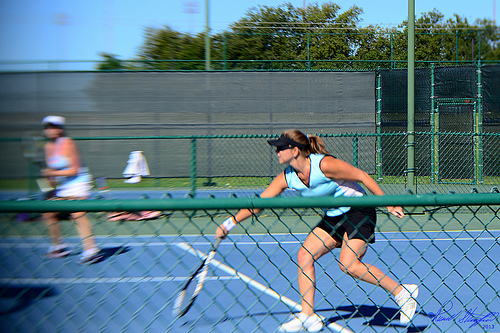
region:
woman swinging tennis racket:
[174, 126, 424, 330]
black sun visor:
[264, 127, 319, 154]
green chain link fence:
[46, 217, 411, 317]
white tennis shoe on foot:
[390, 277, 422, 322]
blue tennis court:
[415, 247, 493, 311]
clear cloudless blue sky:
[17, 8, 148, 49]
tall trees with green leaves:
[197, 12, 377, 61]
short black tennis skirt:
[305, 202, 384, 246]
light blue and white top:
[272, 154, 362, 219]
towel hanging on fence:
[119, 145, 159, 187]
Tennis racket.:
[159, 218, 222, 319]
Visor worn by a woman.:
[258, 127, 328, 164]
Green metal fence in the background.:
[2, 123, 495, 178]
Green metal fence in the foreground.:
[6, 171, 486, 323]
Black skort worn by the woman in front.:
[310, 206, 394, 250]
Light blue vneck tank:
[269, 160, 369, 213]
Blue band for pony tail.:
[298, 122, 314, 143]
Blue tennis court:
[8, 238, 498, 320]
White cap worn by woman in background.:
[38, 114, 68, 137]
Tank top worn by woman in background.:
[40, 134, 84, 178]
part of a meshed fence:
[346, 278, 433, 323]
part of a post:
[278, 198, 315, 214]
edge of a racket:
[188, 285, 206, 313]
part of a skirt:
[346, 215, 378, 243]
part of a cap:
[265, 131, 285, 150]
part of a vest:
[307, 149, 325, 189]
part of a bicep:
[335, 162, 361, 182]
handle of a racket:
[205, 240, 225, 263]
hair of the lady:
[303, 125, 328, 142]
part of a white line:
[233, 265, 263, 305]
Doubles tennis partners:
[30, 105, 416, 330]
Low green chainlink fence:
[1, 190, 491, 320]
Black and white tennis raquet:
[167, 235, 227, 320]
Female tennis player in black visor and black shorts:
[211, 127, 416, 327]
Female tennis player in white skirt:
[20, 110, 105, 261]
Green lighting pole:
[402, 0, 413, 195]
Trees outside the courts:
[135, 1, 495, 58]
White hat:
[37, 111, 63, 126]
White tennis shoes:
[275, 281, 415, 327]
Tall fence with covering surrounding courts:
[2, 65, 492, 180]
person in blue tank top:
[166, 118, 423, 332]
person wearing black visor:
[157, 113, 442, 331]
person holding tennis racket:
[175, 113, 431, 332]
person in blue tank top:
[22, 81, 129, 281]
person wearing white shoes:
[170, 113, 457, 331]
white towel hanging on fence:
[115, 141, 168, 189]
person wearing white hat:
[22, 101, 119, 278]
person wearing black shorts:
[168, 108, 446, 331]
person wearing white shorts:
[28, 103, 113, 270]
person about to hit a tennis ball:
[174, 124, 457, 331]